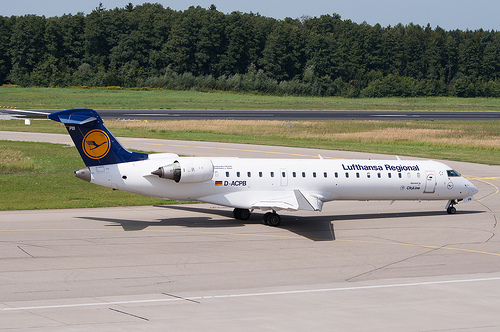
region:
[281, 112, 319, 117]
section of a run way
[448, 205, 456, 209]
front wheel of an aeroplane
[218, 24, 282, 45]
section of a forest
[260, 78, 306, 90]
portion of a bushy plantation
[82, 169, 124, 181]
back part of an aeroplane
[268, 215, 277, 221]
back wheel of an aeroplane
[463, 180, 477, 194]
front part of an aeroplane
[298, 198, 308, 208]
wing of an aeroplane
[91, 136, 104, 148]
yellow patch of an aeroplane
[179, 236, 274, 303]
section of a tarmac road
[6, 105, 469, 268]
this is a plane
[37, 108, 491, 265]
the plane is white in color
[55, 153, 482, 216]
the plane is white in color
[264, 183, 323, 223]
this is the left wing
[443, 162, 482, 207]
the head is streamlined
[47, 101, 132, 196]
this is the tail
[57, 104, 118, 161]
the tail is blue in color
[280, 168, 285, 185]
the door is closed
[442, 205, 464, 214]
the wheel is on the ground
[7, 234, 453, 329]
the run way is clean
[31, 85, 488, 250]
airplane on the ground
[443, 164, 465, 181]
cockpit window on an airplane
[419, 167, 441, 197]
door on an airplane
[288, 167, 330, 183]
side windows on an airplane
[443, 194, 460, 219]
front wheels of an airplane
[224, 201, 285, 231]
landing gear on an airplane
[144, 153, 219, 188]
engine on an airplane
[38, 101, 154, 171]
tail wing on an airplane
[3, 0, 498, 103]
green trees behind a runway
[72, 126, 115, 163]
logo on an airplane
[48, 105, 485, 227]
white plane on runway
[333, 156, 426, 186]
name of airline in blue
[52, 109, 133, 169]
blue and gold on tail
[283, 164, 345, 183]
windows on side of plane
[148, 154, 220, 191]
jet engine on side of plane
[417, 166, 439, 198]
door on front side of plane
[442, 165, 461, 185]
window of cockpit on front of plane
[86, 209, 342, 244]
shadow of plane on runway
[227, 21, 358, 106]
trees on edge of grass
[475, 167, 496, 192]
yellow lines on tarmac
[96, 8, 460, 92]
this is forest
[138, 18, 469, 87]
the forest is green in color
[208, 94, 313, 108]
this is grass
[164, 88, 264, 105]
the grass is green in color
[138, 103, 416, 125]
this is a runway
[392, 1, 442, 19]
this is the sky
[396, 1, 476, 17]
the sky is blue in color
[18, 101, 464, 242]
this is aplane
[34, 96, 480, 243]
the plane is white in color and blue at at the tail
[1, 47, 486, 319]
this is an airport